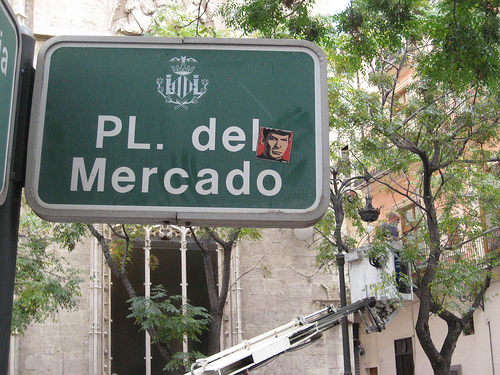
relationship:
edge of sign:
[1, 1, 24, 216] [36, 26, 332, 233]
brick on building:
[369, 192, 403, 206] [323, 34, 499, 374]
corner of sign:
[1, 1, 24, 216] [22, 165, 70, 225]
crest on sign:
[154, 53, 211, 110] [36, 26, 332, 233]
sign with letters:
[36, 26, 332, 233] [70, 116, 286, 198]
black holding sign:
[1, 19, 34, 375] [36, 26, 332, 233]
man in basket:
[371, 207, 407, 247] [345, 239, 416, 312]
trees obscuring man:
[216, 3, 499, 374] [371, 207, 407, 247]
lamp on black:
[359, 194, 384, 233] [334, 172, 381, 374]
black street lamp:
[334, 172, 381, 374] [359, 194, 384, 233]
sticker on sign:
[258, 129, 294, 163] [36, 26, 332, 233]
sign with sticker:
[36, 26, 332, 233] [258, 129, 294, 163]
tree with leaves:
[320, 1, 499, 371] [319, 1, 498, 316]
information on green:
[70, 116, 286, 198] [36, 26, 332, 233]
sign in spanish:
[36, 26, 332, 233] [70, 116, 286, 198]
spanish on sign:
[70, 116, 286, 198] [36, 26, 332, 233]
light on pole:
[359, 194, 384, 233] [330, 159, 380, 374]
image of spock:
[255, 126, 293, 163] [258, 129, 294, 163]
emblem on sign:
[154, 53, 211, 110] [36, 26, 332, 233]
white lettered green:
[70, 116, 286, 198] [36, 26, 332, 233]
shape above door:
[141, 252, 162, 273] [109, 237, 221, 374]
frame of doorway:
[89, 220, 245, 374] [109, 237, 221, 374]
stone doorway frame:
[89, 222, 245, 374] [89, 220, 245, 374]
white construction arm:
[164, 297, 374, 374] [176, 295, 378, 374]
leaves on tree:
[319, 1, 498, 316] [320, 1, 499, 371]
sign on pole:
[36, 26, 332, 233] [1, 23, 38, 248]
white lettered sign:
[70, 116, 286, 198] [36, 26, 332, 233]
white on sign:
[70, 116, 286, 198] [36, 26, 332, 233]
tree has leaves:
[320, 1, 499, 371] [319, 1, 498, 316]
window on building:
[395, 336, 413, 374] [323, 34, 499, 374]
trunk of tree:
[422, 354, 464, 373] [320, 1, 499, 371]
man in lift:
[371, 207, 407, 247] [182, 237, 419, 374]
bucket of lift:
[345, 239, 416, 312] [2, 237, 417, 374]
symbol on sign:
[154, 53, 211, 110] [36, 26, 332, 233]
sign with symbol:
[36, 26, 332, 233] [154, 53, 211, 110]